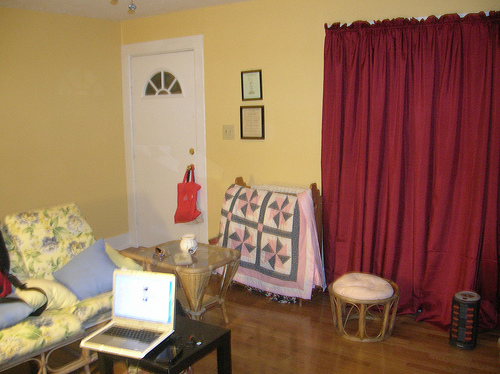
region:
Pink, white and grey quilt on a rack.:
[215, 183, 327, 303]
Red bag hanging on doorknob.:
[171, 163, 204, 227]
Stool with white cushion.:
[326, 268, 402, 344]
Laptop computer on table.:
[76, 268, 176, 361]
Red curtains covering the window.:
[317, 9, 497, 335]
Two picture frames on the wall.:
[238, 68, 264, 140]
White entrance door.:
[118, 35, 212, 273]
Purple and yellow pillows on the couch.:
[1, 239, 128, 330]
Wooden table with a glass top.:
[123, 237, 243, 332]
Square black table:
[93, 311, 233, 371]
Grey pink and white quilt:
[219, 182, 316, 298]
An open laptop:
[86, 265, 173, 361]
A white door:
[122, 35, 206, 259]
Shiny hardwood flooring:
[224, 290, 499, 372]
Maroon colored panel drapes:
[321, 10, 498, 327]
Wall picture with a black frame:
[239, 67, 264, 101]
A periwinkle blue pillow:
[58, 238, 119, 297]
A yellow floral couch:
[0, 200, 147, 369]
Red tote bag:
[175, 161, 202, 224]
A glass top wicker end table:
[125, 233, 242, 322]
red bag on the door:
[169, 159, 203, 229]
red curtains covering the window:
[312, 10, 498, 335]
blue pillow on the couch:
[50, 235, 122, 300]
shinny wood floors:
[236, 319, 315, 371]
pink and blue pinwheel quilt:
[218, 171, 326, 301]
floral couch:
[0, 200, 130, 370]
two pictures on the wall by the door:
[238, 69, 265, 141]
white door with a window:
[114, 37, 213, 256]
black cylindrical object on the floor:
[448, 289, 480, 351]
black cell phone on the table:
[151, 344, 188, 368]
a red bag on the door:
[165, 154, 209, 226]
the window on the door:
[131, 58, 188, 103]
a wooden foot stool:
[321, 262, 406, 348]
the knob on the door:
[181, 160, 198, 172]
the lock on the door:
[180, 142, 200, 157]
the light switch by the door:
[213, 115, 238, 145]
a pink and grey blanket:
[207, 164, 329, 314]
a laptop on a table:
[66, 262, 193, 365]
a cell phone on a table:
[148, 338, 188, 368]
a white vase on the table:
[170, 229, 212, 261]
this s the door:
[130, 54, 212, 210]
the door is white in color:
[133, 104, 165, 137]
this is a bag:
[173, 177, 208, 219]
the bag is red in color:
[174, 193, 196, 211]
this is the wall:
[6, 49, 108, 160]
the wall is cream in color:
[18, 52, 118, 165]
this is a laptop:
[93, 279, 175, 344]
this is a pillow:
[61, 245, 113, 277]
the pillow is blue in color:
[76, 262, 102, 284]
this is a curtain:
[316, 42, 444, 232]